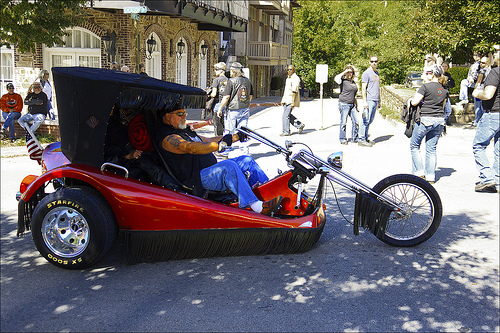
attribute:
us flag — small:
[12, 130, 49, 164]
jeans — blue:
[198, 153, 272, 212]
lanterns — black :
[145, 33, 208, 56]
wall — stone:
[4, 6, 217, 104]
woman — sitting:
[2, 79, 37, 151]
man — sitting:
[154, 99, 271, 214]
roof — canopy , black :
[52, 56, 214, 115]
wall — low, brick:
[338, 64, 450, 128]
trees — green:
[288, 0, 499, 87]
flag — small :
[21, 131, 41, 168]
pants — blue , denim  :
[198, 145, 274, 212]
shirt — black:
[417, 82, 448, 123]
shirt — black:
[340, 77, 355, 107]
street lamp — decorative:
[143, 33, 158, 59]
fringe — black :
[121, 218, 322, 266]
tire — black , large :
[30, 191, 113, 272]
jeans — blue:
[200, 152, 268, 209]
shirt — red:
[1, 91, 22, 111]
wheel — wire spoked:
[358, 181, 439, 240]